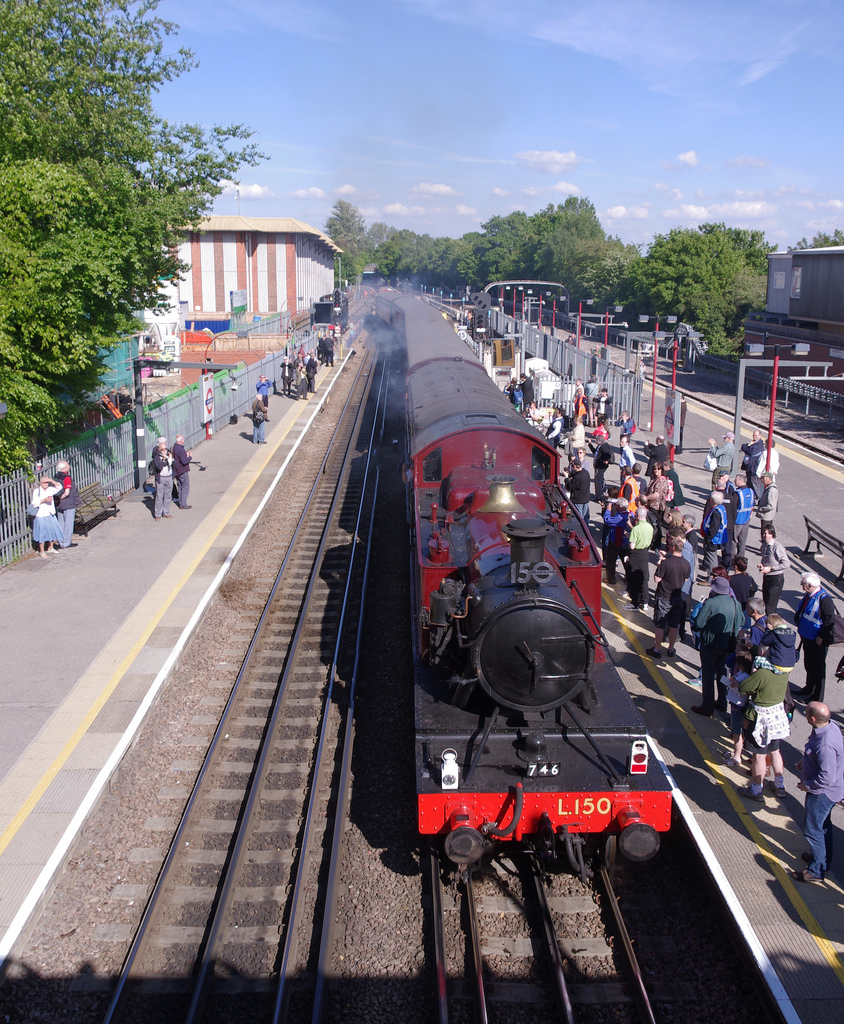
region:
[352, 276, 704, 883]
THE ENGINE IS BLACK AND RED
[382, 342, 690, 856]
THIS IS AN ENGINE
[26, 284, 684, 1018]
THE TRACKS ARE LONG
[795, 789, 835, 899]
THE MAN IS WEARING JEANS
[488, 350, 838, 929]
THE PEOPLE ARE WAITING TO GET ON THE TRAIN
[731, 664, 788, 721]
THE PERSON IS WEARING A GREEN SHIRT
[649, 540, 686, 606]
the person is standing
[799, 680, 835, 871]
the person is standing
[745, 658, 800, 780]
the person is standing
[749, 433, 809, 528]
the person is standing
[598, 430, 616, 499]
the person is standing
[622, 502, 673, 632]
the person is standing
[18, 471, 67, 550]
the person is standing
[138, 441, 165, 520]
the person is standing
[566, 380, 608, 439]
the person is standing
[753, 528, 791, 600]
the person is standing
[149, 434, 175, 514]
person is waiting for a train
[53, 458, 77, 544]
person is waiting for a train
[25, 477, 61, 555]
person is waiting for a train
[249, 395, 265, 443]
person is waiting for a train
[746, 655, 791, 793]
person is waiting for a train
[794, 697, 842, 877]
person is waiting for a train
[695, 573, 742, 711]
person is waiting for a train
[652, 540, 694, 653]
person is waiting for a train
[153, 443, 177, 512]
person is waiting for a train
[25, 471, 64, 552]
person is waiting for a train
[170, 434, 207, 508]
person is waiting for a train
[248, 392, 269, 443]
person is waiting for a train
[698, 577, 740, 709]
person is waiting for a train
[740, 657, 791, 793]
person is waiting for a train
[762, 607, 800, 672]
person is waiting for a train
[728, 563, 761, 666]
a person standing outside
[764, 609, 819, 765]
a person standing outside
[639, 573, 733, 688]
a person standing outside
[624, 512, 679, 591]
a person standing outside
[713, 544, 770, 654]
a person standing outside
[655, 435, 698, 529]
a person standing outside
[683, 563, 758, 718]
A person is standing up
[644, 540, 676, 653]
A person is standing up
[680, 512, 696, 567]
A person is standing up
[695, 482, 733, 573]
A person is standing up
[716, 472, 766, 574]
A person is standing up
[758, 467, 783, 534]
A person is standing up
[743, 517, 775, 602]
A person is standing up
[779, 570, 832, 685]
A person is standing up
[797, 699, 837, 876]
A person is standing up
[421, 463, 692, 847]
The train is red and black.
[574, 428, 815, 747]
Peoople standing on the platform.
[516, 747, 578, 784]
Number 746 in front of the train.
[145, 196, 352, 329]
A building in the background.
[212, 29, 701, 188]
The sky is blue.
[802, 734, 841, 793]
The man is wearing a blue shirt.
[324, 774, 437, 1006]
Gravel in between the tracks.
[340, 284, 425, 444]
Smoke coming from the train.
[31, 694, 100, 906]
A white line on the edge of the platform.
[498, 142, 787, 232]
Clouds in the sky.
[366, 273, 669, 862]
A red train at the station.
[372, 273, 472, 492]
Smoke over the train.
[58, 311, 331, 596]
People waiting behind a yellow line.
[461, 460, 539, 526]
A gold bell on the train.